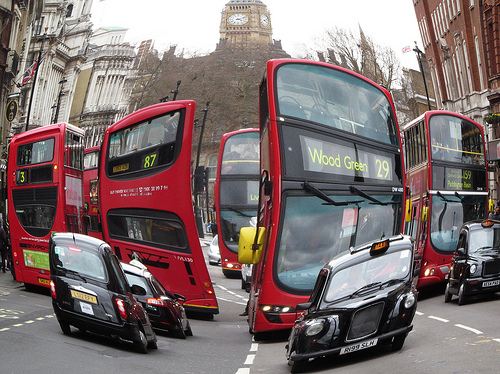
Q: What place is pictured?
A: It is a road.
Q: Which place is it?
A: It is a road.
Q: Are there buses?
A: Yes, there is a bus.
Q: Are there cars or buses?
A: Yes, there is a bus.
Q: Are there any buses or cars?
A: Yes, there is a bus.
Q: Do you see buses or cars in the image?
A: Yes, there is a bus.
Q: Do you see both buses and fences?
A: No, there is a bus but no fences.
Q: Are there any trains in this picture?
A: No, there are no trains.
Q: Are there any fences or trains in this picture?
A: No, there are no trains or fences.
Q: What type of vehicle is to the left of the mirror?
A: The vehicle is a bus.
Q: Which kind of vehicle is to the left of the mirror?
A: The vehicle is a bus.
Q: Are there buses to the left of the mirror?
A: Yes, there is a bus to the left of the mirror.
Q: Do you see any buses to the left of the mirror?
A: Yes, there is a bus to the left of the mirror.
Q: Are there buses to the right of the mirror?
A: No, the bus is to the left of the mirror.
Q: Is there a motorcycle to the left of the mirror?
A: No, there is a bus to the left of the mirror.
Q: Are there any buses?
A: Yes, there is a bus.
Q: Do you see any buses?
A: Yes, there is a bus.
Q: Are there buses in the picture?
A: Yes, there is a bus.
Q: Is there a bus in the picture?
A: Yes, there is a bus.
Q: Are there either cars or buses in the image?
A: Yes, there is a bus.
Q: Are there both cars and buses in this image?
A: Yes, there are both a bus and a car.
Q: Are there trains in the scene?
A: No, there are no trains.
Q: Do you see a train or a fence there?
A: No, there are no trains or fences.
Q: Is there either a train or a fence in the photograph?
A: No, there are no trains or fences.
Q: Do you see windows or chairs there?
A: Yes, there is a window.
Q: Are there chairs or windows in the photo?
A: Yes, there is a window.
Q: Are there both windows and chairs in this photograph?
A: No, there is a window but no chairs.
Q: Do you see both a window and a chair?
A: No, there is a window but no chairs.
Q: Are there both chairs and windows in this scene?
A: No, there is a window but no chairs.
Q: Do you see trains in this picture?
A: No, there are no trains.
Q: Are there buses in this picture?
A: Yes, there is a bus.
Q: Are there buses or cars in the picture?
A: Yes, there is a bus.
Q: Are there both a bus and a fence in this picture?
A: No, there is a bus but no fences.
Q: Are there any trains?
A: No, there are no trains.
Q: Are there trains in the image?
A: No, there are no trains.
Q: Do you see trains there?
A: No, there are no trains.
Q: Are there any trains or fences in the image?
A: No, there are no trains or fences.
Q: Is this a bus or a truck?
A: This is a bus.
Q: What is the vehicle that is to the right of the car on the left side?
A: The vehicle is a bus.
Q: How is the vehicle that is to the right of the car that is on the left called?
A: The vehicle is a bus.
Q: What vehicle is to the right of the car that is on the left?
A: The vehicle is a bus.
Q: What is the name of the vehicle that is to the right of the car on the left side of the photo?
A: The vehicle is a bus.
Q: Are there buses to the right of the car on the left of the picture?
A: Yes, there is a bus to the right of the car.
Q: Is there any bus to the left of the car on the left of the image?
A: No, the bus is to the right of the car.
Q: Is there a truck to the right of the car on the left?
A: No, there is a bus to the right of the car.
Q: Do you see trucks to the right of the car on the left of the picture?
A: No, there is a bus to the right of the car.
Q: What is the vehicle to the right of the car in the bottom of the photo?
A: The vehicle is a bus.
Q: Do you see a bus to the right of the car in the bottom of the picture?
A: Yes, there is a bus to the right of the car.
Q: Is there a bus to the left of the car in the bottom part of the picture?
A: No, the bus is to the right of the car.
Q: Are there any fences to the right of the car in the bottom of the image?
A: No, there is a bus to the right of the car.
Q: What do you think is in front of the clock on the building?
A: The bus is in front of the clock.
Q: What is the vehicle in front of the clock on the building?
A: The vehicle is a bus.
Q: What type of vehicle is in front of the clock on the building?
A: The vehicle is a bus.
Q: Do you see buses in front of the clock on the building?
A: Yes, there is a bus in front of the clock.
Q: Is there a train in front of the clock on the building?
A: No, there is a bus in front of the clock.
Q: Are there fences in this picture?
A: No, there are no fences.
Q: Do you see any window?
A: Yes, there is a window.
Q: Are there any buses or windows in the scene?
A: Yes, there is a window.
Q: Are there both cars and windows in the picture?
A: Yes, there are both a window and a car.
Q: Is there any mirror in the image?
A: Yes, there is a mirror.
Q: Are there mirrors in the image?
A: Yes, there is a mirror.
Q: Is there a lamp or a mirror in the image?
A: Yes, there is a mirror.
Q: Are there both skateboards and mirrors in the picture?
A: No, there is a mirror but no skateboards.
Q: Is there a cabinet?
A: No, there are no cabinets.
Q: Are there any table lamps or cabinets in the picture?
A: No, there are no cabinets or table lamps.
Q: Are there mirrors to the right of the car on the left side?
A: Yes, there is a mirror to the right of the car.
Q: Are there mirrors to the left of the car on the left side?
A: No, the mirror is to the right of the car.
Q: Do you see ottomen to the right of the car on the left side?
A: No, there is a mirror to the right of the car.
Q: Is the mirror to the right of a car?
A: Yes, the mirror is to the right of a car.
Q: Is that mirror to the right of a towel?
A: No, the mirror is to the right of a car.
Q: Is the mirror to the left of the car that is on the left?
A: No, the mirror is to the right of the car.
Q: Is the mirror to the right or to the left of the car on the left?
A: The mirror is to the right of the car.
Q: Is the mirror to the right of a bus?
A: Yes, the mirror is to the right of a bus.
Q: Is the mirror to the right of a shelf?
A: No, the mirror is to the right of a bus.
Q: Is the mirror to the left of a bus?
A: No, the mirror is to the right of a bus.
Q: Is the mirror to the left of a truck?
A: No, the mirror is to the left of the car.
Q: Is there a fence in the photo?
A: No, there are no fences.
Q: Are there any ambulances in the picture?
A: No, there are no ambulances.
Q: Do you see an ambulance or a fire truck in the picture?
A: No, there are no ambulances or fire trucks.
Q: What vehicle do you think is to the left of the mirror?
A: The vehicle is a car.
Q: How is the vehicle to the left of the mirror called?
A: The vehicle is a car.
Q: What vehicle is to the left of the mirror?
A: The vehicle is a car.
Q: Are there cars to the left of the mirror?
A: Yes, there is a car to the left of the mirror.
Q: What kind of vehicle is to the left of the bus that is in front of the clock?
A: The vehicle is a car.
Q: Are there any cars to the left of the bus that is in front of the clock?
A: Yes, there is a car to the left of the bus.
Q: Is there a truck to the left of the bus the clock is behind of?
A: No, there is a car to the left of the bus.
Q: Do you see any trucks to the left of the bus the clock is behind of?
A: No, there is a car to the left of the bus.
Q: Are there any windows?
A: Yes, there is a window.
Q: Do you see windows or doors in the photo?
A: Yes, there is a window.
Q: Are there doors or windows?
A: Yes, there is a window.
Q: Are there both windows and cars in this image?
A: Yes, there are both a window and a car.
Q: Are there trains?
A: No, there are no trains.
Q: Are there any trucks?
A: No, there are no trucks.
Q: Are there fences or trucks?
A: No, there are no trucks or fences.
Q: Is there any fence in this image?
A: No, there are no fences.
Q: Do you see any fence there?
A: No, there are no fences.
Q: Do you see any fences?
A: No, there are no fences.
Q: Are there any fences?
A: No, there are no fences.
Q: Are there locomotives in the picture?
A: No, there are no locomotives.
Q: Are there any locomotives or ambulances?
A: No, there are no locomotives or ambulances.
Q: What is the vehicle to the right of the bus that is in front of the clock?
A: The vehicle is a car.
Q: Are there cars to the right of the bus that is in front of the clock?
A: Yes, there is a car to the right of the bus.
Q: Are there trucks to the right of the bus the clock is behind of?
A: No, there is a car to the right of the bus.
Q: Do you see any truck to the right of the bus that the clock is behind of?
A: No, there is a car to the right of the bus.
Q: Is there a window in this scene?
A: Yes, there is a window.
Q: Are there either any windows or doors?
A: Yes, there is a window.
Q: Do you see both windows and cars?
A: Yes, there are both a window and a car.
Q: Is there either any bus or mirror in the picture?
A: Yes, there is a bus.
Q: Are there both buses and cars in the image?
A: Yes, there are both a bus and a car.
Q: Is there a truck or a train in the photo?
A: No, there are no trucks or trains.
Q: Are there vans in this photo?
A: No, there are no vans.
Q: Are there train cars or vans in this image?
A: No, there are no vans or train cars.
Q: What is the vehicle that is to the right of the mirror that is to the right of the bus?
A: The vehicle is a car.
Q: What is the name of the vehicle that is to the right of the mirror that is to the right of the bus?
A: The vehicle is a car.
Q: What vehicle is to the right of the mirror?
A: The vehicle is a car.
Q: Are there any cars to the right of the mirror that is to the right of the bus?
A: Yes, there is a car to the right of the mirror.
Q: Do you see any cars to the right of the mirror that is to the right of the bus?
A: Yes, there is a car to the right of the mirror.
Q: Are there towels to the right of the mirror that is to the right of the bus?
A: No, there is a car to the right of the mirror.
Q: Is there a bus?
A: Yes, there is a bus.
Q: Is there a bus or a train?
A: Yes, there is a bus.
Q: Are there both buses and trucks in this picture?
A: No, there is a bus but no trucks.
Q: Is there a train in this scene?
A: No, there are no trains.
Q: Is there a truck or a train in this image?
A: No, there are no trains or trucks.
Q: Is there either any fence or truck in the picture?
A: No, there are no fences or trucks.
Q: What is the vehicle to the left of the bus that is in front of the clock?
A: The vehicle is a car.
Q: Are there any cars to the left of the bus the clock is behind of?
A: Yes, there is a car to the left of the bus.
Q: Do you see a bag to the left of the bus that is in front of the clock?
A: No, there is a car to the left of the bus.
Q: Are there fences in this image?
A: No, there are no fences.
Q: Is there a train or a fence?
A: No, there are no fences or trains.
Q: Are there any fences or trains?
A: No, there are no fences or trains.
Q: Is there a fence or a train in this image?
A: No, there are no fences or trains.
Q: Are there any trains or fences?
A: No, there are no fences or trains.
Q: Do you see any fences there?
A: No, there are no fences.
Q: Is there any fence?
A: No, there are no fences.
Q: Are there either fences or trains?
A: No, there are no fences or trains.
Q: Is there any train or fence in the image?
A: No, there are no fences or trains.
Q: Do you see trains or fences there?
A: No, there are no fences or trains.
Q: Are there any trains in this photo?
A: No, there are no trains.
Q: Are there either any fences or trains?
A: No, there are no trains or fences.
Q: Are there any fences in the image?
A: No, there are no fences.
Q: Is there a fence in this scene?
A: No, there are no fences.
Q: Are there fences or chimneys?
A: No, there are no fences or chimneys.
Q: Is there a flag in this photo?
A: Yes, there is a flag.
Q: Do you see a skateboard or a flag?
A: Yes, there is a flag.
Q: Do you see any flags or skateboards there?
A: Yes, there is a flag.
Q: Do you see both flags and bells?
A: No, there is a flag but no bells.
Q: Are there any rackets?
A: No, there are no rackets.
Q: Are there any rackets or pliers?
A: No, there are no rackets or pliers.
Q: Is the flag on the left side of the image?
A: Yes, the flag is on the left of the image.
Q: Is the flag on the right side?
A: No, the flag is on the left of the image.